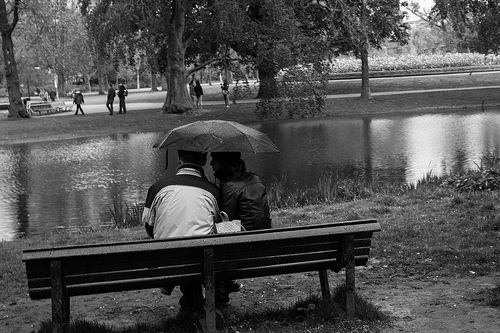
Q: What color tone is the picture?
A: Black and white.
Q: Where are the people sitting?
A: On a bench.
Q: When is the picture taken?
A: Daytime.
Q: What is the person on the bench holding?
A: An umbrella.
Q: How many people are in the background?
A: 6.